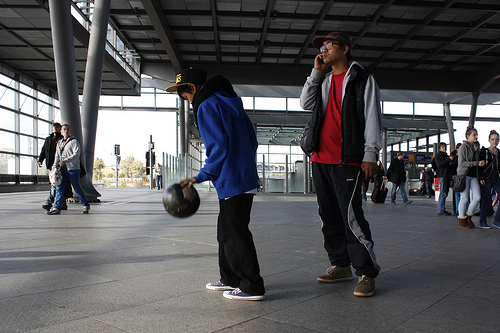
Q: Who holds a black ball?
A: A boy.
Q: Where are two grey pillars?
A: In a building.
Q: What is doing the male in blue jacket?
A: Bouncing a ball.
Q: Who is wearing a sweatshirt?
A: A boy.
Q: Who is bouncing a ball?
A: A young boy.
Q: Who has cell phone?
A: A young man.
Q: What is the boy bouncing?
A: A ball.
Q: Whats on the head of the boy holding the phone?
A: A baseball cap.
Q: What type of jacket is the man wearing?
A: Long sleeves.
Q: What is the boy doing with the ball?
A: Bouncing.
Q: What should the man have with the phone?
A: Bluetooth.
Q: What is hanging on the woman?
A: Purse.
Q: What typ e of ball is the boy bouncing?
A: Soccer.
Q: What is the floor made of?
A: Concrete.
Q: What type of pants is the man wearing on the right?
A: Jeans.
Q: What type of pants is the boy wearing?
A: Workout.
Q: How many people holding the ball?
A: One.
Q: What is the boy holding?
A: A ball.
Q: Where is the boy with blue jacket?
A: At the station.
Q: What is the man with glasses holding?
A: A phone.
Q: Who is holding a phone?
A: Man with glasses.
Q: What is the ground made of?
A: Cement.